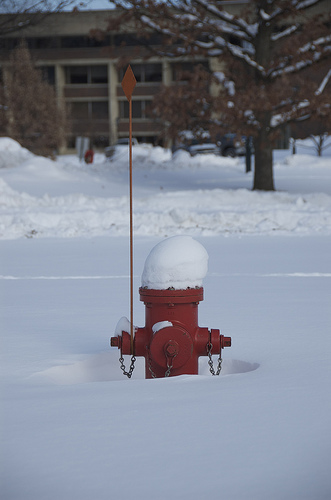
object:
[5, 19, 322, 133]
background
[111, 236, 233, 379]
fire hydrant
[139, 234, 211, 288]
snow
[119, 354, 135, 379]
chain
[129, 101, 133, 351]
pole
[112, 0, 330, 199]
tree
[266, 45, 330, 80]
branches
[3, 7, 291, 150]
building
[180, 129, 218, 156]
truck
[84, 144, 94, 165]
person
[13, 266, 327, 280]
line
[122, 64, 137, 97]
diamond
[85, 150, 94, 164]
shirt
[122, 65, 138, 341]
flag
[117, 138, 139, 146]
vehicle